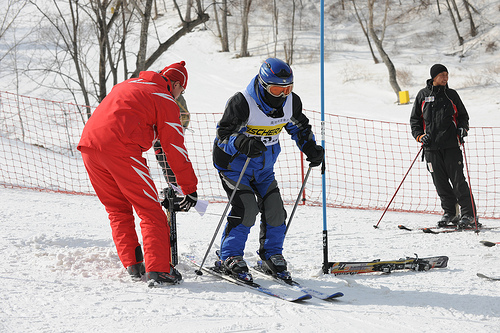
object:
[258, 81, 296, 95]
goggles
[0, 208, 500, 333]
ground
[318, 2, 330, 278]
blue pole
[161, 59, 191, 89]
hat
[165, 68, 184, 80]
stripe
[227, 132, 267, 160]
gloves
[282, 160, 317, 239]
poles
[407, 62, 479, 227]
man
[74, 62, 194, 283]
man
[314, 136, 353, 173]
wall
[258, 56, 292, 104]
helmet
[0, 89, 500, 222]
fencing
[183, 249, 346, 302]
ski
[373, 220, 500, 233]
ski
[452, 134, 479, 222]
ski pole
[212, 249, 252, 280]
boots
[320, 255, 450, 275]
ski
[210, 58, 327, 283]
man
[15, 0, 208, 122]
tree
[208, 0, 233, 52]
tree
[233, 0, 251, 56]
tree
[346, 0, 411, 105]
tree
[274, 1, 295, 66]
tree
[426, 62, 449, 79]
cap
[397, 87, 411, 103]
object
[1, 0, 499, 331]
snow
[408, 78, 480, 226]
clothing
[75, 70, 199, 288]
outfit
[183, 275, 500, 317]
shadows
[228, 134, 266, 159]
skier's hand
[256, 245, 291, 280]
skier's feet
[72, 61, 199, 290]
gear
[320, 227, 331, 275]
base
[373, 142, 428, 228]
poles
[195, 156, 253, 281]
poles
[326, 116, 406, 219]
net